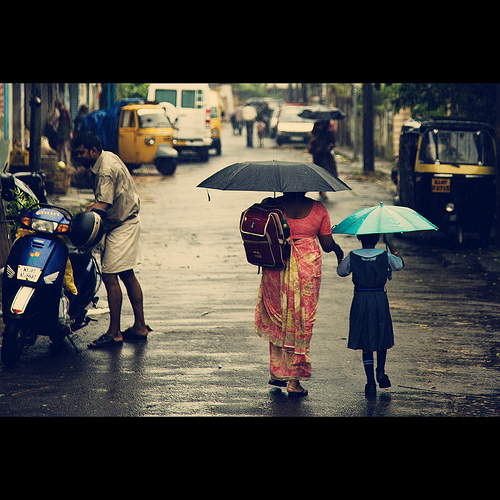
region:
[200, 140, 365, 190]
woman holding gray umbrella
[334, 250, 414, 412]
girl wearing school uniform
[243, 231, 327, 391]
pink sari on woman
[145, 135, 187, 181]
blue wheel on mini taxi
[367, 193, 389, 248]
spokes in blue umbrella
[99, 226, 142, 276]
wrinkles in man's shorts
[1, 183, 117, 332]
shiny neon blue bike parked on the road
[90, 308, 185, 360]
man wearing black sneakers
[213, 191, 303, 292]
black and red back pack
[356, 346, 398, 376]
long sleeve black socks with white stripe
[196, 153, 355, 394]
woman holding black umbrella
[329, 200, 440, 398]
young girl holding blue umbrella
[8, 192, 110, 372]
scooter with metallic blue paint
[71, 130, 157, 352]
man wearing khaki outfit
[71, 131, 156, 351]
man wearing black sandals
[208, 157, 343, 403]
woman wearing coral sari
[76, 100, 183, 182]
yellow tuk tuk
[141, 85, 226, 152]
large white van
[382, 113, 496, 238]
tuk tuk with black and gold paint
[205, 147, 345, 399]
woman carrying a maroon backpack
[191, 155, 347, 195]
a large black umbrella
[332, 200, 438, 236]
a small green umbrella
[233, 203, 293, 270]
a red and white backpack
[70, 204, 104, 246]
a motorcycle helmet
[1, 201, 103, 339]
a blue motorcycle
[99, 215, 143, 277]
men's white shorts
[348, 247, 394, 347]
a girl's blue uniform dress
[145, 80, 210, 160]
a white cargo van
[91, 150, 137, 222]
a man's gray short sleeve shirt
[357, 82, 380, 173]
a long pole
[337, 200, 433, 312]
child holding blue umbrella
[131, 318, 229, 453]
rain on the road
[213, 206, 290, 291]
brown and maroon backpack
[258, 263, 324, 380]
pink green and yellow skirt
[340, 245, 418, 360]
light blue shirt and dark dress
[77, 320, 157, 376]
black sandals on feet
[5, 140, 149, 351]
person beside a motor scooter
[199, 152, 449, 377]
two people walking in the rain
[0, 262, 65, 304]
white stickers that are wings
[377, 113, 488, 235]
yellow and black vehicle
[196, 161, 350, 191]
a black canopy of an umbrella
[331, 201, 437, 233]
a green canopy of an umbrella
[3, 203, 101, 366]
a blue scooter on the side of the road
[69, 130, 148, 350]
a man standing next to the scooter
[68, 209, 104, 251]
a motorcycle helmet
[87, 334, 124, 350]
the man is wearing sandals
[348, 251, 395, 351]
a girl wearing a blue school uniform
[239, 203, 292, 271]
a lady carrying a red and white backpack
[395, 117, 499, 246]
a tuk tuk three wheel taxi in india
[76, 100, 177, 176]
a yellow tuk tuk three wheel scooter